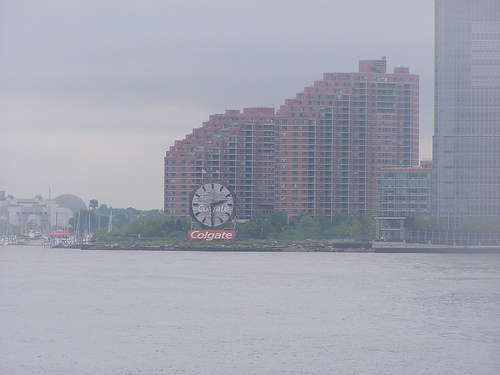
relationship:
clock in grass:
[178, 180, 248, 240] [246, 212, 353, 247]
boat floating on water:
[3, 234, 29, 249] [8, 242, 497, 369]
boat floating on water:
[13, 230, 46, 241] [8, 242, 497, 369]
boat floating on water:
[41, 231, 76, 248] [8, 242, 497, 369]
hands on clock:
[207, 195, 231, 228] [191, 183, 236, 228]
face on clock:
[191, 178, 234, 232] [185, 178, 235, 255]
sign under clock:
[184, 231, 233, 242] [189, 174, 238, 231]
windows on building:
[314, 118, 354, 201] [269, 51, 430, 222]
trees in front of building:
[115, 210, 377, 242] [157, 53, 422, 230]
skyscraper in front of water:
[432, 5, 499, 237] [364, 255, 464, 335]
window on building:
[172, 172, 182, 183] [161, 101, 287, 221]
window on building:
[239, 124, 256, 147] [5, 26, 432, 236]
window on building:
[241, 148, 252, 154] [162, 53, 420, 253]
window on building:
[237, 180, 254, 191] [161, 101, 287, 221]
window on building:
[242, 193, 253, 203] [139, 50, 421, 246]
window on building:
[242, 170, 254, 183] [139, 50, 421, 246]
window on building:
[240, 146, 257, 158] [139, 50, 421, 246]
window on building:
[210, 165, 217, 171] [139, 50, 421, 246]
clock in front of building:
[189, 180, 237, 229] [162, 53, 420, 253]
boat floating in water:
[41, 230, 74, 246] [8, 242, 497, 369]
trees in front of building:
[88, 203, 375, 245] [157, 53, 422, 230]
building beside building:
[157, 53, 422, 230] [434, 0, 498, 244]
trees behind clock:
[104, 197, 381, 251] [189, 180, 237, 229]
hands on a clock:
[210, 203, 215, 228] [183, 164, 260, 276]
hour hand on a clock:
[208, 188, 228, 213] [183, 164, 260, 276]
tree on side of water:
[327, 215, 356, 242] [8, 242, 497, 369]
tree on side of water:
[296, 214, 323, 240] [8, 242, 497, 369]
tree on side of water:
[236, 215, 268, 243] [8, 242, 497, 369]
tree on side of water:
[125, 213, 161, 240] [8, 242, 497, 369]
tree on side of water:
[90, 226, 110, 244] [8, 242, 497, 369]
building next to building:
[157, 53, 422, 230] [376, 1, 498, 245]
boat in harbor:
[41, 230, 74, 246] [4, 236, 496, 372]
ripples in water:
[0, 246, 217, 372] [8, 242, 497, 369]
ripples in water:
[27, 262, 295, 362] [8, 242, 497, 369]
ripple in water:
[130, 322, 184, 332] [8, 242, 497, 369]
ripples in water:
[169, 320, 287, 372] [2, 249, 497, 374]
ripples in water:
[274, 277, 366, 318] [8, 242, 497, 369]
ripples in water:
[275, 342, 304, 353] [8, 242, 497, 369]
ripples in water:
[308, 326, 353, 361] [2, 230, 498, 373]